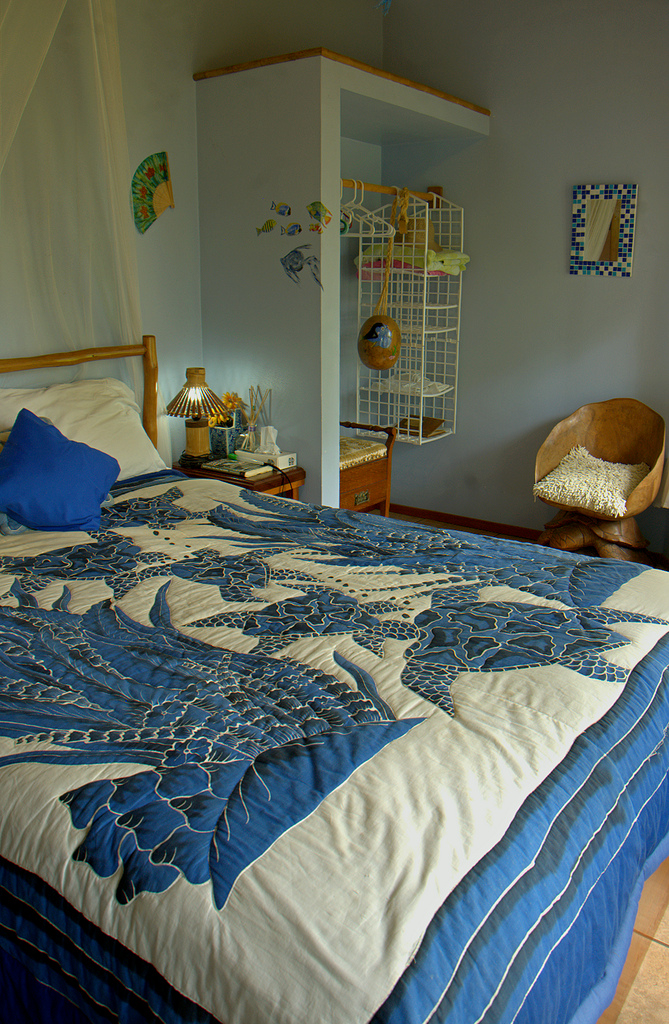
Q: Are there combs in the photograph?
A: No, there are no combs.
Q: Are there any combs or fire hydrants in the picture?
A: No, there are no combs or fire hydrants.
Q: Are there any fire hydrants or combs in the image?
A: No, there are no combs or fire hydrants.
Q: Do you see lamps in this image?
A: Yes, there is a lamp.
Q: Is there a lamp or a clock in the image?
A: Yes, there is a lamp.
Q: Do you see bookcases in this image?
A: No, there are no bookcases.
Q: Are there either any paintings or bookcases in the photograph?
A: No, there are no bookcases or paintings.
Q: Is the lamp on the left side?
A: Yes, the lamp is on the left of the image.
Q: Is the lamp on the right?
A: No, the lamp is on the left of the image.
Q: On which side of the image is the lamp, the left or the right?
A: The lamp is on the left of the image.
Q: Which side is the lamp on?
A: The lamp is on the left of the image.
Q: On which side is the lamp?
A: The lamp is on the left of the image.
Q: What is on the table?
A: The lamp is on the table.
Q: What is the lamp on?
A: The lamp is on the table.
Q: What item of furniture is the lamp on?
A: The lamp is on the table.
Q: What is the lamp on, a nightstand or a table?
A: The lamp is on a table.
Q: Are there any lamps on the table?
A: Yes, there is a lamp on the table.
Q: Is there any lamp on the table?
A: Yes, there is a lamp on the table.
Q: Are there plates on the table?
A: No, there is a lamp on the table.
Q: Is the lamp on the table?
A: Yes, the lamp is on the table.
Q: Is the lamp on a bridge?
A: No, the lamp is on the table.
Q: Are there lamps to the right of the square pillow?
A: Yes, there is a lamp to the right of the pillow.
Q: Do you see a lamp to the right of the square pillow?
A: Yes, there is a lamp to the right of the pillow.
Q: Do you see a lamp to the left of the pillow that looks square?
A: No, the lamp is to the right of the pillow.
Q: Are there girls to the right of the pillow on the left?
A: No, there is a lamp to the right of the pillow.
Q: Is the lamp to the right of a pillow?
A: Yes, the lamp is to the right of a pillow.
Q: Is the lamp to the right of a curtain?
A: No, the lamp is to the right of a pillow.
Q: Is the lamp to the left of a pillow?
A: No, the lamp is to the right of a pillow.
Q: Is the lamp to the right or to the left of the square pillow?
A: The lamp is to the right of the pillow.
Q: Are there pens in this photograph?
A: No, there are no pens.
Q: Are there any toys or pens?
A: No, there are no pens or toys.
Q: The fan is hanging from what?
A: The fan is hanging from the wall.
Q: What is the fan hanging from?
A: The fan is hanging from the wall.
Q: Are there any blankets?
A: Yes, there is a blanket.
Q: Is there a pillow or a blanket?
A: Yes, there is a blanket.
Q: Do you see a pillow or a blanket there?
A: Yes, there is a blanket.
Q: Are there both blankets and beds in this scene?
A: Yes, there are both a blanket and a bed.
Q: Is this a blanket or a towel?
A: This is a blanket.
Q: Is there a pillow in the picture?
A: Yes, there is a pillow.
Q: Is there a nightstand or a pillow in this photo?
A: Yes, there is a pillow.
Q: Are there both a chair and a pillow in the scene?
A: Yes, there are both a pillow and a chair.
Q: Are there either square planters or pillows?
A: Yes, there is a square pillow.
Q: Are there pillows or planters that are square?
A: Yes, the pillow is square.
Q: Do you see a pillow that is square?
A: Yes, there is a square pillow.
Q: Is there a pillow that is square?
A: Yes, there is a pillow that is square.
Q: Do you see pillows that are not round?
A: Yes, there is a square pillow.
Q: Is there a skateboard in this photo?
A: No, there are no skateboards.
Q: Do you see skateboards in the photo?
A: No, there are no skateboards.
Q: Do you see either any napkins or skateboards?
A: No, there are no skateboards or napkins.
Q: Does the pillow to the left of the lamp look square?
A: Yes, the pillow is square.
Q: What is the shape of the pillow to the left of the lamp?
A: The pillow is square.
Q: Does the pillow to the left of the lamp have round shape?
A: No, the pillow is square.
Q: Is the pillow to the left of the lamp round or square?
A: The pillow is square.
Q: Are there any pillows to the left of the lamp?
A: Yes, there is a pillow to the left of the lamp.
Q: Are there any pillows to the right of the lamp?
A: No, the pillow is to the left of the lamp.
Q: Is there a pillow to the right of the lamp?
A: No, the pillow is to the left of the lamp.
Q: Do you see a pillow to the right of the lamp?
A: No, the pillow is to the left of the lamp.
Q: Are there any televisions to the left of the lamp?
A: No, there is a pillow to the left of the lamp.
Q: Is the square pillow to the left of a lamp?
A: Yes, the pillow is to the left of a lamp.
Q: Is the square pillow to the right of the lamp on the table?
A: No, the pillow is to the left of the lamp.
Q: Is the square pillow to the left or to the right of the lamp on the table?
A: The pillow is to the left of the lamp.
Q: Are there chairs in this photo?
A: Yes, there is a chair.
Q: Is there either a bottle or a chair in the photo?
A: Yes, there is a chair.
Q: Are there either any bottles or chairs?
A: Yes, there is a chair.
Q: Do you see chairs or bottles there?
A: Yes, there is a chair.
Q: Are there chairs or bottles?
A: Yes, there is a chair.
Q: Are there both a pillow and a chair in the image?
A: Yes, there are both a chair and a pillow.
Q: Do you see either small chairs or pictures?
A: Yes, there is a small chair.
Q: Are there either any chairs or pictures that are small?
A: Yes, the chair is small.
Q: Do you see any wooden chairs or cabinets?
A: Yes, there is a wood chair.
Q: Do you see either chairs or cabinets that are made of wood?
A: Yes, the chair is made of wood.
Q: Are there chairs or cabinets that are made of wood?
A: Yes, the chair is made of wood.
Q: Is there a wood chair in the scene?
A: Yes, there is a wood chair.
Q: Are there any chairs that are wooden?
A: Yes, there is a chair that is wooden.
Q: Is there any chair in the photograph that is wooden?
A: Yes, there is a chair that is wooden.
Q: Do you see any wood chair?
A: Yes, there is a chair that is made of wood.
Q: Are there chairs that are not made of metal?
A: Yes, there is a chair that is made of wood.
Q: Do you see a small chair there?
A: Yes, there is a small chair.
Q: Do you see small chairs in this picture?
A: Yes, there is a small chair.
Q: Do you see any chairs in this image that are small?
A: Yes, there is a chair that is small.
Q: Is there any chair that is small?
A: Yes, there is a chair that is small.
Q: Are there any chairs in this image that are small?
A: Yes, there is a chair that is small.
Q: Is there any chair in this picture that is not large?
A: Yes, there is a small chair.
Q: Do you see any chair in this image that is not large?
A: Yes, there is a small chair.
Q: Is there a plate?
A: No, there are no plates.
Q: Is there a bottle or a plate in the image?
A: No, there are no plates or bottles.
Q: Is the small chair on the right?
A: Yes, the chair is on the right of the image.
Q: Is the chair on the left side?
A: No, the chair is on the right of the image.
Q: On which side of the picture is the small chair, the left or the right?
A: The chair is on the right of the image.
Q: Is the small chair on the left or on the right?
A: The chair is on the right of the image.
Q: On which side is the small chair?
A: The chair is on the right of the image.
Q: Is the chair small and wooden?
A: Yes, the chair is small and wooden.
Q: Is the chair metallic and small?
A: No, the chair is small but wooden.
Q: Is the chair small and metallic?
A: No, the chair is small but wooden.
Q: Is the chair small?
A: Yes, the chair is small.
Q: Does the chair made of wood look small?
A: Yes, the chair is small.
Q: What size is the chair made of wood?
A: The chair is small.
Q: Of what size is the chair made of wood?
A: The chair is small.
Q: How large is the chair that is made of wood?
A: The chair is small.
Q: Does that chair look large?
A: No, the chair is small.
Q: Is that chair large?
A: No, the chair is small.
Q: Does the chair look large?
A: No, the chair is small.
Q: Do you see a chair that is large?
A: No, there is a chair but it is small.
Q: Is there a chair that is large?
A: No, there is a chair but it is small.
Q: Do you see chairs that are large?
A: No, there is a chair but it is small.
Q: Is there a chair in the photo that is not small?
A: No, there is a chair but it is small.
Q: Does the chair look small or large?
A: The chair is small.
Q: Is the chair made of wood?
A: Yes, the chair is made of wood.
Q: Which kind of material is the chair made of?
A: The chair is made of wood.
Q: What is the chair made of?
A: The chair is made of wood.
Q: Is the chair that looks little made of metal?
A: No, the chair is made of wood.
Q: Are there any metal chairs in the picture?
A: No, there is a chair but it is made of wood.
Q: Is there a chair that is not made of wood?
A: No, there is a chair but it is made of wood.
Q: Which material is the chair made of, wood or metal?
A: The chair is made of wood.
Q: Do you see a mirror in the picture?
A: Yes, there is a mirror.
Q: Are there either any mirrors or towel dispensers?
A: Yes, there is a mirror.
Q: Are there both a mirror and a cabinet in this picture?
A: No, there is a mirror but no cabinets.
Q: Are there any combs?
A: No, there are no combs.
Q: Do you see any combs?
A: No, there are no combs.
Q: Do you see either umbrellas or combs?
A: No, there are no combs or umbrellas.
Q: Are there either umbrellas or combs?
A: No, there are no combs or umbrellas.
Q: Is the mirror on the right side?
A: Yes, the mirror is on the right of the image.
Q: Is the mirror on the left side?
A: No, the mirror is on the right of the image.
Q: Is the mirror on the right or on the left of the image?
A: The mirror is on the right of the image.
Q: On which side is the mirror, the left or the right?
A: The mirror is on the right of the image.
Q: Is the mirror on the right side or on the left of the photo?
A: The mirror is on the right of the image.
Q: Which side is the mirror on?
A: The mirror is on the right of the image.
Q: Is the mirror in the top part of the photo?
A: Yes, the mirror is in the top of the image.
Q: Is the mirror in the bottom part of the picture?
A: No, the mirror is in the top of the image.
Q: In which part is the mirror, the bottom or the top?
A: The mirror is in the top of the image.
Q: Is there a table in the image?
A: Yes, there is a table.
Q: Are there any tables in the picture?
A: Yes, there is a table.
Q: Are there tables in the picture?
A: Yes, there is a table.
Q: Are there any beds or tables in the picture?
A: Yes, there is a table.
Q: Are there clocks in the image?
A: No, there are no clocks.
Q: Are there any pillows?
A: Yes, there is a pillow.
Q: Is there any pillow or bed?
A: Yes, there is a pillow.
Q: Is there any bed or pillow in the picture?
A: Yes, there is a pillow.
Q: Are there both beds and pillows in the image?
A: Yes, there are both a pillow and a bed.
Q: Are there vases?
A: No, there are no vases.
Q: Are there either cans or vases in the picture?
A: No, there are no vases or cans.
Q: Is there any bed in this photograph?
A: Yes, there is a bed.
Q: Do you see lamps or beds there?
A: Yes, there is a bed.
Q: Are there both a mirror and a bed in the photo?
A: Yes, there are both a bed and a mirror.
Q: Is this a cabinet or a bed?
A: This is a bed.